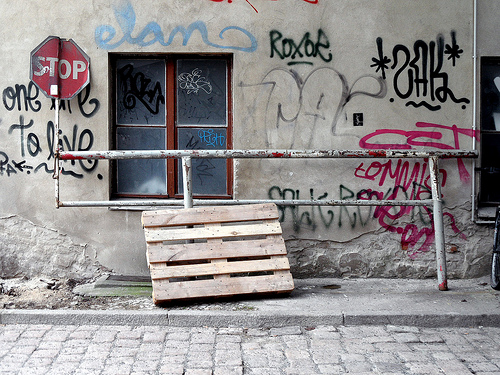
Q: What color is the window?
A: Brown.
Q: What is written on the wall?
A: Words.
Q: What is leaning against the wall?
A: A wooden block.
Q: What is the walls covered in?
A: Graffiti.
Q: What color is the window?
A: Brown.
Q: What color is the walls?
A: Grey.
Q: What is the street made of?
A: Brick.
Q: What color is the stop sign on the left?
A: Red.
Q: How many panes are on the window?
A: Four.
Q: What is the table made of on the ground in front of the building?
A: Wood.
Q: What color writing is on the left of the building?
A: Black.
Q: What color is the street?
A: Grey.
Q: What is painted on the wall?
A: Graffiti.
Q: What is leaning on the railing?
A: A pallet.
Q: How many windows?
A: One.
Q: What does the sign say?
A: Stop.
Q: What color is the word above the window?
A: Blue.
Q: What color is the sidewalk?
A: Gray.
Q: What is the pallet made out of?
A: Wood.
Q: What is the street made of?
A: Cobblestone.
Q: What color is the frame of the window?
A: Brown.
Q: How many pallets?
A: One.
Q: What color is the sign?
A: Red.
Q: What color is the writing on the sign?
A: White.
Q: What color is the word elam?
A: Blue.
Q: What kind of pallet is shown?
A: Wooden.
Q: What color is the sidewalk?
A: Gray.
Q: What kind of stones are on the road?
A: Cobblestone.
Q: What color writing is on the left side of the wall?
A: Black.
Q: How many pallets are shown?
A: One.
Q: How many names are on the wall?
A: 2.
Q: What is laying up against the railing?
A: Pallet.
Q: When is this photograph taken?
A: During the morning.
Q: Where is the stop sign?
A: To the left.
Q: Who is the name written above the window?
A: Elan.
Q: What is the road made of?
A: Cobblestone.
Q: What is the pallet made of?
A: Wood.